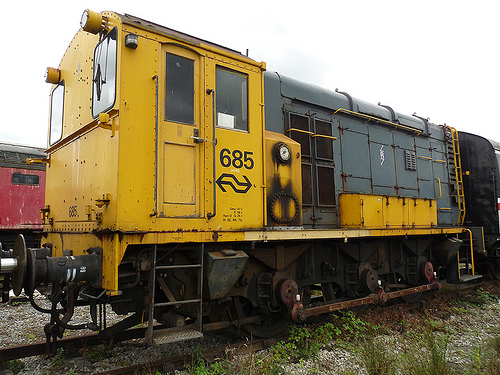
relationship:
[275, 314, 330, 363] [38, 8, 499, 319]
weed on side of train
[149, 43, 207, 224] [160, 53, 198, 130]
door has window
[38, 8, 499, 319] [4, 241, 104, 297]
train has plugs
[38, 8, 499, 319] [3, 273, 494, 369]
train on track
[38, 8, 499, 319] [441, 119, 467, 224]
train has ladder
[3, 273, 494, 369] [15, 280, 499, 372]
track on ground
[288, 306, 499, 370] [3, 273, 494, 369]
gravel next to track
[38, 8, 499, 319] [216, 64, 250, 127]
train has window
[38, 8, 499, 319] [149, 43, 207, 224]
train has door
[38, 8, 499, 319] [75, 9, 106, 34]
train has light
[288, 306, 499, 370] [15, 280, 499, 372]
gravel on ground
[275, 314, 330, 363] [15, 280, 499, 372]
weed on ground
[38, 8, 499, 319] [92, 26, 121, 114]
train has window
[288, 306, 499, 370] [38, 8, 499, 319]
gravel under train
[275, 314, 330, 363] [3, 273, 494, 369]
weed along side track